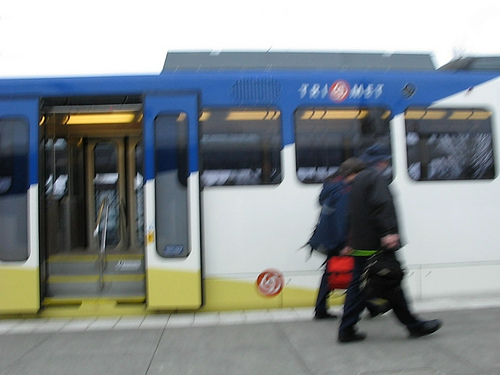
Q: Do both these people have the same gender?
A: No, they are both male and female.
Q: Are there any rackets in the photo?
A: No, there are no rackets.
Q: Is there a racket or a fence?
A: No, there are no rackets or fences.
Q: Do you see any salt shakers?
A: No, there are no salt shakers.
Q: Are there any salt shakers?
A: No, there are no salt shakers.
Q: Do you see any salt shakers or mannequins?
A: No, there are no salt shakers or mannequins.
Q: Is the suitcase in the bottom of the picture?
A: Yes, the suitcase is in the bottom of the image.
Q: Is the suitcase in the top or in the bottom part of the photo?
A: The suitcase is in the bottom of the image.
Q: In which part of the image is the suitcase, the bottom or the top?
A: The suitcase is in the bottom of the image.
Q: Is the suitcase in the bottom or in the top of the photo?
A: The suitcase is in the bottom of the image.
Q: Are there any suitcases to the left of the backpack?
A: Yes, there is a suitcase to the left of the backpack.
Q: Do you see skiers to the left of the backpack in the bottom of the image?
A: No, there is a suitcase to the left of the backpack.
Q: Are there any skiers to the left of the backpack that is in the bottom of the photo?
A: No, there is a suitcase to the left of the backpack.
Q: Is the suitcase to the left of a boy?
A: No, the suitcase is to the left of the backpack.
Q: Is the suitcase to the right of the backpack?
A: No, the suitcase is to the left of the backpack.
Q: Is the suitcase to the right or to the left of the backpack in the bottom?
A: The suitcase is to the left of the backpack.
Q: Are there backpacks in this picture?
A: Yes, there is a backpack.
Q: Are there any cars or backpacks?
A: Yes, there is a backpack.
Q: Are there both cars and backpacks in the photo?
A: No, there is a backpack but no cars.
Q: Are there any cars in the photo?
A: No, there are no cars.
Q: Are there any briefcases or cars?
A: No, there are no cars or briefcases.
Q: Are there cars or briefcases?
A: No, there are no cars or briefcases.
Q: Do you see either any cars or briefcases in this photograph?
A: No, there are no cars or briefcases.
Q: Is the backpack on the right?
A: Yes, the backpack is on the right of the image.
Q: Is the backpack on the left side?
A: No, the backpack is on the right of the image.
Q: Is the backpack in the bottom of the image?
A: Yes, the backpack is in the bottom of the image.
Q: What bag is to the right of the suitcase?
A: The bag is a backpack.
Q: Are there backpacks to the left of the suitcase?
A: No, the backpack is to the right of the suitcase.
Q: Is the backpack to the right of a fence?
A: No, the backpack is to the right of the suitcase.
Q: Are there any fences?
A: No, there are no fences.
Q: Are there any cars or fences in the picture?
A: No, there are no fences or cars.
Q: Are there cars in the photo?
A: No, there are no cars.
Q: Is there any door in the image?
A: Yes, there is a door.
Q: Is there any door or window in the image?
A: Yes, there is a door.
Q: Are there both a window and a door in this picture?
A: Yes, there are both a door and a window.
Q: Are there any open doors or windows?
A: Yes, there is an open door.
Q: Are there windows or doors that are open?
A: Yes, the door is open.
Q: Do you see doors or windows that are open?
A: Yes, the door is open.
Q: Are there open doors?
A: Yes, there is an open door.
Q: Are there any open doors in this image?
A: Yes, there is an open door.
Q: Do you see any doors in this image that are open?
A: Yes, there is a door that is open.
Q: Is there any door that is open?
A: Yes, there is a door that is open.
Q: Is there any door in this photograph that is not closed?
A: Yes, there is a open door.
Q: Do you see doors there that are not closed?
A: Yes, there is a open door.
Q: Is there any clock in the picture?
A: No, there are no clocks.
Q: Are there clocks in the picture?
A: No, there are no clocks.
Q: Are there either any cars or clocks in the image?
A: No, there are no clocks or cars.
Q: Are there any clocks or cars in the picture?
A: No, there are no clocks or cars.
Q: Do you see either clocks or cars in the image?
A: No, there are no clocks or cars.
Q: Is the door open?
A: Yes, the door is open.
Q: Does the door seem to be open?
A: Yes, the door is open.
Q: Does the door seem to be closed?
A: No, the door is open.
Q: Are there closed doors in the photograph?
A: No, there is a door but it is open.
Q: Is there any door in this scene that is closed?
A: No, there is a door but it is open.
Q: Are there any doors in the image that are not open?
A: No, there is a door but it is open.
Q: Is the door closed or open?
A: The door is open.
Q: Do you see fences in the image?
A: No, there are no fences.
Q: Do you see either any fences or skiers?
A: No, there are no fences or skiers.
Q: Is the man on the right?
A: Yes, the man is on the right of the image.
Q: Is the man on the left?
A: No, the man is on the right of the image.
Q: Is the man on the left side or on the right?
A: The man is on the right of the image.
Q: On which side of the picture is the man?
A: The man is on the right of the image.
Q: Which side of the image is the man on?
A: The man is on the right of the image.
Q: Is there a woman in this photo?
A: Yes, there is a woman.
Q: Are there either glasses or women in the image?
A: Yes, there is a woman.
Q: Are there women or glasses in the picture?
A: Yes, there is a woman.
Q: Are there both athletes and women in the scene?
A: No, there is a woman but no athletes.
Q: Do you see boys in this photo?
A: No, there are no boys.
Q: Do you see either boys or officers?
A: No, there are no boys or officers.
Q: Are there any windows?
A: Yes, there is a window.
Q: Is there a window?
A: Yes, there is a window.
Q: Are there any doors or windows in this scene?
A: Yes, there is a window.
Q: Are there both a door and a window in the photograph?
A: Yes, there are both a window and a door.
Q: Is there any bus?
A: No, there are no buses.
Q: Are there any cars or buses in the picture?
A: No, there are no buses or cars.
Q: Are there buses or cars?
A: No, there are no buses or cars.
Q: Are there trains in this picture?
A: Yes, there is a train.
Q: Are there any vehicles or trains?
A: Yes, there is a train.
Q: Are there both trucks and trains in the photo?
A: No, there is a train but no trucks.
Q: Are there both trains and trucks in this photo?
A: No, there is a train but no trucks.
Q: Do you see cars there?
A: No, there are no cars.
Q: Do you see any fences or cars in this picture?
A: No, there are no cars or fences.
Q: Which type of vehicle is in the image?
A: The vehicle is a train.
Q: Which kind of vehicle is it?
A: The vehicle is a train.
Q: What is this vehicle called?
A: That is a train.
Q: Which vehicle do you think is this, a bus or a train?
A: That is a train.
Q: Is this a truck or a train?
A: This is a train.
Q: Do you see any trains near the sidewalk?
A: Yes, there is a train near the sidewalk.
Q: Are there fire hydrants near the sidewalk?
A: No, there is a train near the sidewalk.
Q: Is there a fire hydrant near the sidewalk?
A: No, there is a train near the sidewalk.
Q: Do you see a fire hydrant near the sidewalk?
A: No, there is a train near the sidewalk.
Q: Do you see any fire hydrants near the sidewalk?
A: No, there is a train near the sidewalk.